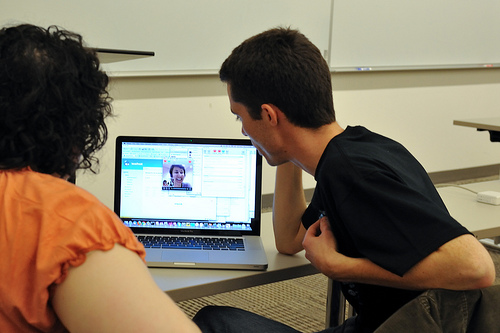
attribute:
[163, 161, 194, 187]
face — Watching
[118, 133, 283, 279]
computer — turned on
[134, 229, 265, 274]
keyboard — black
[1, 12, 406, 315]
two people — sitting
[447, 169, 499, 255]
part — Gray